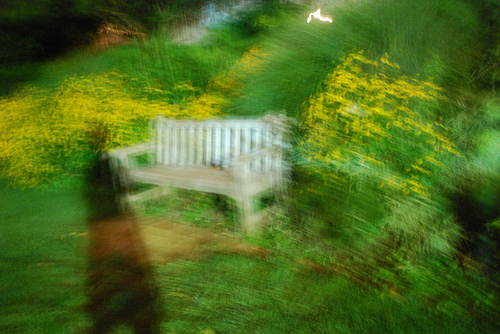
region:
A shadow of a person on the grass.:
[85, 121, 159, 332]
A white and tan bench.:
[107, 114, 286, 232]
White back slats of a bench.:
[154, 114, 285, 170]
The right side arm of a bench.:
[229, 145, 284, 165]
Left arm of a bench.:
[106, 138, 156, 160]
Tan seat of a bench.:
[131, 158, 273, 195]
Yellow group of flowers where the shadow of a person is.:
[1, 75, 217, 179]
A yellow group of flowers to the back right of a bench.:
[299, 50, 460, 183]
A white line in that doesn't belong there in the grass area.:
[305, 6, 332, 24]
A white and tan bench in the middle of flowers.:
[108, 115, 290, 232]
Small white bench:
[100, 103, 300, 246]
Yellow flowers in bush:
[289, 39, 464, 225]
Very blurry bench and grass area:
[10, 6, 497, 328]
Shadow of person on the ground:
[72, 120, 170, 332]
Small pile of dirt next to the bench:
[72, 181, 301, 303]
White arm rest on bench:
[102, 138, 159, 170]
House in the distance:
[12, 0, 144, 62]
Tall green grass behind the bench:
[204, 4, 498, 146]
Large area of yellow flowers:
[2, 53, 258, 185]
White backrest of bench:
[148, 103, 289, 172]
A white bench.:
[107, 114, 289, 234]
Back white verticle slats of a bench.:
[153, 116, 285, 170]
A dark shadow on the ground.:
[83, 115, 158, 332]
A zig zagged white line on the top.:
[304, 8, 331, 27]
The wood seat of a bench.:
[131, 158, 273, 190]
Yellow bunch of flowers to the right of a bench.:
[301, 45, 456, 190]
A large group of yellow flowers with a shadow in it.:
[3, 77, 232, 189]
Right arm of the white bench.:
[236, 148, 281, 165]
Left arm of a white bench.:
[104, 142, 153, 169]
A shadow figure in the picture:
[56, 118, 192, 329]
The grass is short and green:
[206, 278, 486, 328]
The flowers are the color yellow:
[302, 70, 415, 147]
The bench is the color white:
[113, 105, 320, 236]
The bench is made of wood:
[127, 104, 299, 233]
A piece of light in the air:
[301, 3, 338, 31]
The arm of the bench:
[228, 135, 276, 183]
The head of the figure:
[78, 115, 120, 155]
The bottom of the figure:
[78, 242, 170, 331]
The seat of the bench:
[143, 155, 227, 200]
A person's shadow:
[67, 119, 170, 329]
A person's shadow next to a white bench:
[65, 88, 296, 332]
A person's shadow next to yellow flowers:
[26, 84, 156, 333]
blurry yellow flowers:
[22, 91, 69, 221]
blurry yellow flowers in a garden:
[17, 39, 83, 321]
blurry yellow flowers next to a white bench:
[152, 54, 432, 237]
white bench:
[148, 109, 308, 249]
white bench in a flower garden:
[155, 87, 417, 271]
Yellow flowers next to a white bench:
[131, 67, 393, 219]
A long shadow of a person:
[58, 101, 175, 333]